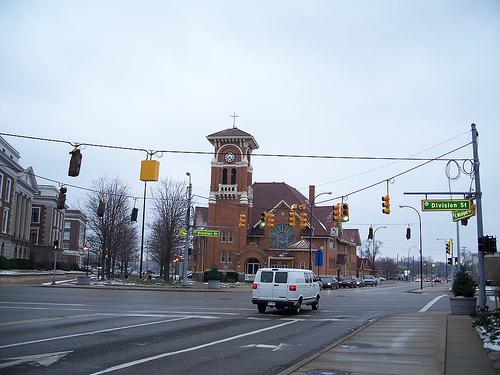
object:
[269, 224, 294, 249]
window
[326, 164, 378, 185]
ground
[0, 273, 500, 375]
street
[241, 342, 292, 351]
arrow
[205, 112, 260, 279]
clock tower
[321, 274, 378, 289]
traffic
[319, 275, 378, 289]
car line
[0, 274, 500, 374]
pavement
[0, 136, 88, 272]
building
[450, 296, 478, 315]
pot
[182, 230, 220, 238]
signs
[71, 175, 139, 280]
tree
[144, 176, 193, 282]
tree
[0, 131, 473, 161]
cable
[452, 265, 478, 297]
tree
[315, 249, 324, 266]
sign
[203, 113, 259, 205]
steeple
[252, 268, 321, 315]
van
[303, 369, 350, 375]
covers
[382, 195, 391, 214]
traffic light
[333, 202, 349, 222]
traffic light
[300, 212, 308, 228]
traffic light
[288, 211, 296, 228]
traffic light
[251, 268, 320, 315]
traffic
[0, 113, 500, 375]
city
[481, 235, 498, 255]
crosswalk signal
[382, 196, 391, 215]
stop light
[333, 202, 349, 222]
stop light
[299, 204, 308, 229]
stop light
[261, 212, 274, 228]
stop light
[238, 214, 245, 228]
stop light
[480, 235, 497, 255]
light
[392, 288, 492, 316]
corner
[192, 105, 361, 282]
church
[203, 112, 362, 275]
building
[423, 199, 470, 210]
sign